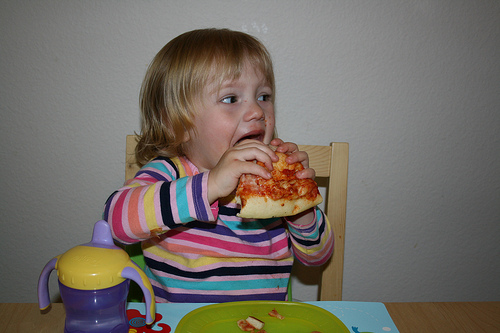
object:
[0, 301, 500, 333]
table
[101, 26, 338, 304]
child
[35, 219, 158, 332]
cup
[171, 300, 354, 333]
plate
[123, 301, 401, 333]
place mat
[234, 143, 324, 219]
pizza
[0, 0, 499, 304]
wall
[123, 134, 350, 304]
chair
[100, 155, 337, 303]
shirt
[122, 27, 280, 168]
hair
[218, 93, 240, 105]
eyes